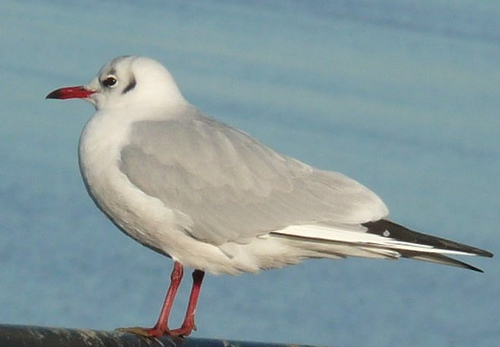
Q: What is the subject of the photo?
A: Bird.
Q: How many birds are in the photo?
A: One.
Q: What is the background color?
A: Blue.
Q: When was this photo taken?
A: Daytime.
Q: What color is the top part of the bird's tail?
A: Black.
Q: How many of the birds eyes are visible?
A: One.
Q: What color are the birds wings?
A: Grey.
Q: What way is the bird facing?
A: Left.